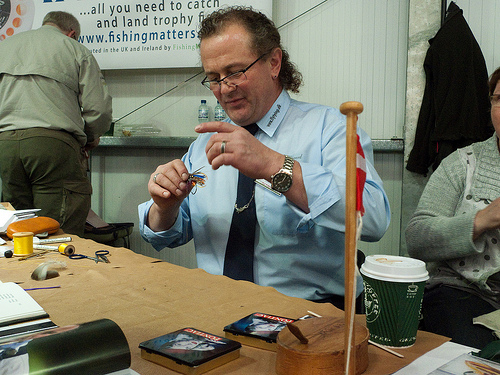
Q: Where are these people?
A: At a fishing event.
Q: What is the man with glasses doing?
A: Tying a fly.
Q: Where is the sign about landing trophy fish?
A: Behind the man.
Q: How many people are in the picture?
A: Three.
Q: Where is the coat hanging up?
A: Behind the woman.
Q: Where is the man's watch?
A: On his wrist.